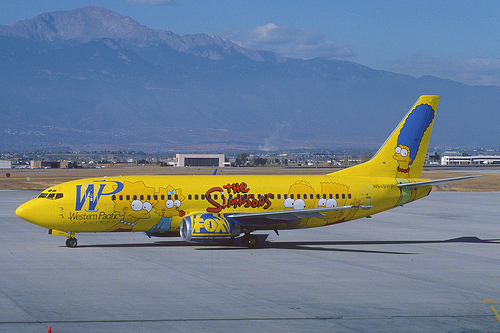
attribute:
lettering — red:
[206, 180, 271, 211]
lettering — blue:
[73, 176, 121, 211]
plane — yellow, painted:
[14, 93, 474, 247]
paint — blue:
[395, 105, 435, 160]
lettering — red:
[208, 179, 276, 212]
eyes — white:
[163, 197, 183, 208]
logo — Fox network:
[188, 211, 231, 236]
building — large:
[169, 151, 222, 166]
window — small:
[108, 192, 118, 203]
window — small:
[117, 194, 125, 203]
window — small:
[126, 192, 132, 204]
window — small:
[131, 190, 139, 203]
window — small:
[146, 192, 153, 202]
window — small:
[149, 193, 159, 202]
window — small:
[158, 191, 167, 203]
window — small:
[164, 193, 174, 201]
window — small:
[186, 191, 194, 202]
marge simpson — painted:
[391, 104, 435, 206]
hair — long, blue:
[396, 102, 436, 163]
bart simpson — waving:
[318, 181, 362, 225]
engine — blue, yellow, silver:
[177, 211, 237, 243]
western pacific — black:
[67, 209, 123, 220]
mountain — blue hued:
[0, 3, 499, 149]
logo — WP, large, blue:
[72, 178, 123, 211]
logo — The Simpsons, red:
[205, 179, 275, 214]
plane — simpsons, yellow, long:
[7, 78, 457, 291]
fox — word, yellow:
[189, 210, 233, 240]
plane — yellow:
[18, 79, 463, 261]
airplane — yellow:
[35, 62, 450, 288]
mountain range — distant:
[20, 6, 380, 152]